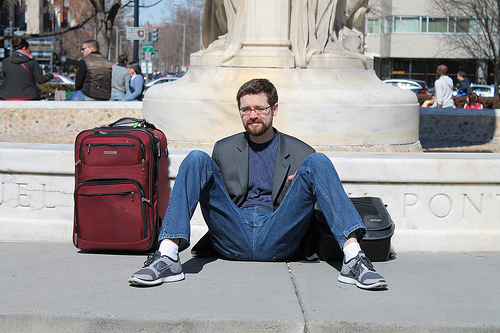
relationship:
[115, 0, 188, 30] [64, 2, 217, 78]
sky behind trees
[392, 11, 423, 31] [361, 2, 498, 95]
window on building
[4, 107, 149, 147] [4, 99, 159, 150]
rocks on wall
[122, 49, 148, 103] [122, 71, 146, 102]
woman in shirt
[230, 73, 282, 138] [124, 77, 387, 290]
head in man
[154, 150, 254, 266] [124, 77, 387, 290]
leg on man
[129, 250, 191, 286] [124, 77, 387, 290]
feet on man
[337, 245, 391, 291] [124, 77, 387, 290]
feet on man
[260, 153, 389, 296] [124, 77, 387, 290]
leg on man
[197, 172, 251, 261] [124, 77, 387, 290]
thigh on man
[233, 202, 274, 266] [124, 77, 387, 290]
croch on man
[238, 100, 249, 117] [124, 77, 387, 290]
eye on man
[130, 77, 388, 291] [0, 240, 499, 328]
man sitting on floor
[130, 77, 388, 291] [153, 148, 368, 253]
man wearing jeans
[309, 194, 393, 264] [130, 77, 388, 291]
luggage beside man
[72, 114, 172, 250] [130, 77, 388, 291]
suitcase beside man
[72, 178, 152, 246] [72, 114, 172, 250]
compartment on suitcase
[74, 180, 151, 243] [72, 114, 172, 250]
storage compartment on suitcase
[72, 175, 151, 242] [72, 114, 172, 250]
zipper on suitcase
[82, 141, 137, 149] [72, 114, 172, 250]
zipper on suitcase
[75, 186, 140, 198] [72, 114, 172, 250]
zipper on suitcase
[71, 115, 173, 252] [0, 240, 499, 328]
suitcase on floor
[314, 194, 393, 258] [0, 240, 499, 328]
luggage on floor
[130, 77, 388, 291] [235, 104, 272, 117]
man wearing glasses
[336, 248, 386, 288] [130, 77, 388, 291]
shoe on man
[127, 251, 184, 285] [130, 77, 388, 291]
shoe on man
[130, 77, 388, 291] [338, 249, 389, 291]
man wearing shoe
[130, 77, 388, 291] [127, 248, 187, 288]
man wearing shoe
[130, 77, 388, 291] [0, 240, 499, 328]
man sitting floor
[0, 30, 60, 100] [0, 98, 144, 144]
person sitting on wall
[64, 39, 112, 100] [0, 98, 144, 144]
person sitting on wall